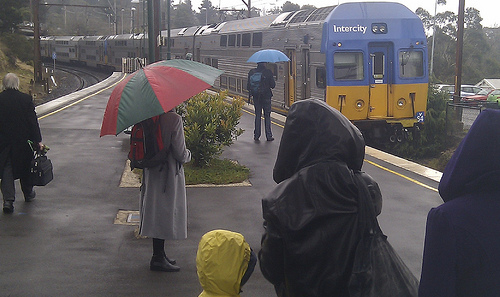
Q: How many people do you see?
A: Six.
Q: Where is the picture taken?
A: Train stop.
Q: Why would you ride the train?
A: To get to your destination quickly.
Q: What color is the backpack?
A: Red.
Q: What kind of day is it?
A: Wet and rainy.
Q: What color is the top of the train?
A: Blue.